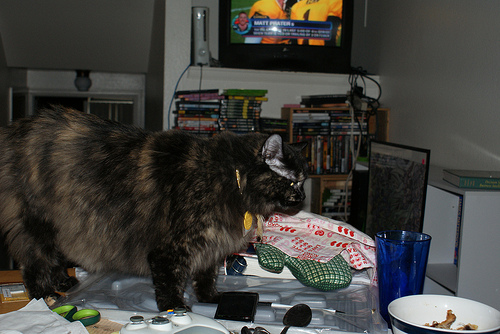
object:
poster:
[363, 140, 433, 242]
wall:
[365, 0, 500, 171]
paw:
[203, 288, 223, 305]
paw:
[170, 303, 197, 315]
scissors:
[50, 301, 102, 324]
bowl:
[387, 293, 500, 334]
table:
[2, 252, 393, 334]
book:
[443, 168, 500, 190]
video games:
[174, 88, 219, 98]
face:
[252, 148, 308, 216]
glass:
[371, 230, 429, 329]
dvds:
[220, 87, 268, 98]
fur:
[22, 129, 86, 186]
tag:
[240, 211, 255, 229]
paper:
[0, 297, 88, 332]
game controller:
[168, 305, 192, 325]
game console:
[192, 4, 212, 63]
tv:
[216, 0, 354, 75]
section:
[259, 261, 352, 289]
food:
[422, 308, 479, 329]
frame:
[361, 140, 430, 240]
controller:
[146, 314, 173, 331]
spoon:
[278, 302, 313, 333]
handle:
[52, 303, 75, 318]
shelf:
[425, 262, 459, 296]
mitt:
[255, 242, 353, 291]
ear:
[260, 135, 289, 163]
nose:
[281, 184, 299, 204]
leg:
[147, 263, 181, 307]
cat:
[0, 98, 308, 314]